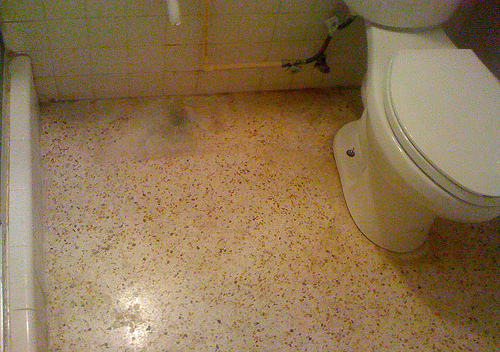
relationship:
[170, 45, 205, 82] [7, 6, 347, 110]
tile on a wall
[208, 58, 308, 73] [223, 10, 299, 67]
pipe on wall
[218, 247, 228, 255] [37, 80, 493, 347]
speck on floor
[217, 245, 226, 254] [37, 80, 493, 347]
speck on floor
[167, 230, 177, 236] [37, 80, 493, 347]
speck on floor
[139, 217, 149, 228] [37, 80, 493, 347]
speck on floor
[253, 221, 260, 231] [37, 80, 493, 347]
speck on floor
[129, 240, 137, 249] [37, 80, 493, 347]
speck on floor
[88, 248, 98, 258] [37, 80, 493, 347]
speck on floor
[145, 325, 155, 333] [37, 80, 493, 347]
speck on floor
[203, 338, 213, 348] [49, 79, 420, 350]
speck on floor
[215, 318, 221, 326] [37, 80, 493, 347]
speck on floor